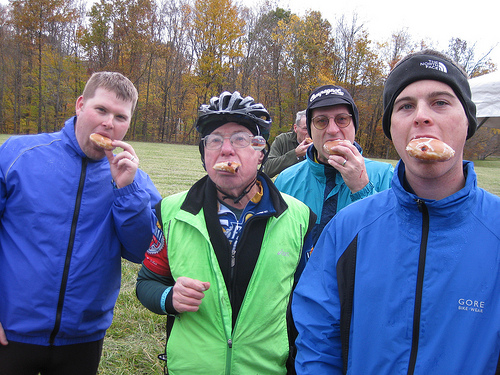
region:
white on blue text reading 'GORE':
[453, 288, 490, 317]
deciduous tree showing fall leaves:
[185, 3, 246, 81]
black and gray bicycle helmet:
[188, 74, 277, 127]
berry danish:
[405, 138, 455, 160]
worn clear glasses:
[201, 128, 259, 149]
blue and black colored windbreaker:
[292, 176, 498, 373]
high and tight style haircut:
[81, 66, 136, 106]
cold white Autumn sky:
[380, 0, 495, 30]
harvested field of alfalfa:
[149, 143, 185, 175]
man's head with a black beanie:
[370, 41, 480, 135]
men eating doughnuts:
[9, 29, 484, 374]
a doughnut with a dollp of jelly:
[213, 157, 251, 184]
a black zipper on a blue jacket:
[399, 230, 430, 367]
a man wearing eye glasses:
[147, 94, 309, 374]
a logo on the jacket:
[448, 292, 497, 322]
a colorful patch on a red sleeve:
[149, 229, 179, 257]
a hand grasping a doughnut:
[83, 134, 154, 176]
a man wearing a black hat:
[309, 80, 356, 151]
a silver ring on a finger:
[337, 151, 352, 171]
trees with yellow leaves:
[151, 80, 186, 146]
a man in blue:
[377, 173, 460, 368]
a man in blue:
[349, 319, 369, 369]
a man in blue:
[377, 226, 468, 316]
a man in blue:
[368, 219, 408, 307]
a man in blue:
[350, 299, 397, 374]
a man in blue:
[354, 204, 404, 326]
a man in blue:
[380, 241, 430, 347]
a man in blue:
[410, 238, 465, 353]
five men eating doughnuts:
[5, 66, 496, 301]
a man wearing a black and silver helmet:
[190, 85, 277, 142]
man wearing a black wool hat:
[378, 49, 479, 120]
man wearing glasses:
[305, 111, 362, 133]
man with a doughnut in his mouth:
[390, 119, 464, 184]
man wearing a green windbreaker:
[158, 186, 310, 373]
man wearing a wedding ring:
[340, 157, 350, 171]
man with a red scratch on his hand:
[355, 164, 368, 184]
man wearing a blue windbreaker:
[3, 132, 140, 356]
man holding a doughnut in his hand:
[79, 127, 158, 182]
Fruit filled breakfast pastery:
[404, 136, 459, 163]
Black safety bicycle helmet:
[195, 89, 272, 126]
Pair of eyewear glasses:
[313, 112, 354, 129]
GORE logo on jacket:
[452, 291, 489, 316]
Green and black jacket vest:
[157, 191, 298, 372]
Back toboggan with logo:
[388, 49, 471, 101]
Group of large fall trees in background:
[138, 3, 192, 140]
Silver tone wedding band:
[340, 158, 352, 165]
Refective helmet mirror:
[251, 123, 269, 152]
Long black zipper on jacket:
[63, 148, 91, 278]